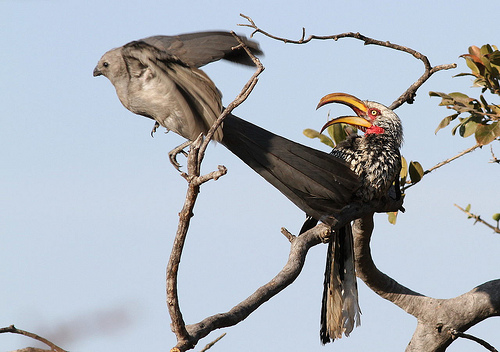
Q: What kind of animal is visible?
A: Birds.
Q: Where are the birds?
A: In a tree.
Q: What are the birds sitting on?
A: Tree branches.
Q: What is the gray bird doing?
A: Flying away.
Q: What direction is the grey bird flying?
A: Left.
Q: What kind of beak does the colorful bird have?
A: Long orange beak.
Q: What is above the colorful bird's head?
A: Thin tree branch.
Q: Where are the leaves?
A: On the branches.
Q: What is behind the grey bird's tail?
A: A colorful bird.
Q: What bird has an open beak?
A: Colorful bird.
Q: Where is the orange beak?
A: On the bird.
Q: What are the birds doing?
A: Sitting.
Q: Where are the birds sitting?
A: A tree branch.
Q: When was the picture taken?
A: Daytime.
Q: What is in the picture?
A: Birds.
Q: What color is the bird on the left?
A: Gray.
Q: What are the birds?
A: In a tree.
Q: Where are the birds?
A: A tree.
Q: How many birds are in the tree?
A: Two.